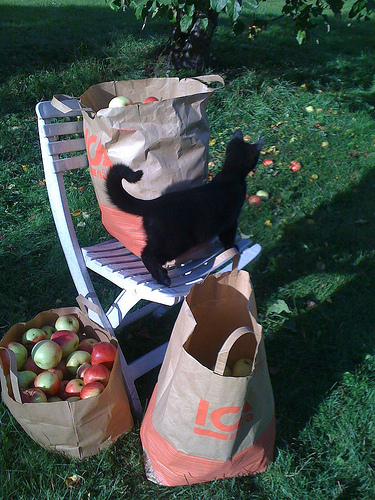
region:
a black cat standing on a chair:
[103, 125, 278, 291]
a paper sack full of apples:
[0, 293, 134, 463]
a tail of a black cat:
[103, 162, 148, 224]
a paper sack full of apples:
[50, 78, 221, 189]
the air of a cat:
[228, 124, 247, 145]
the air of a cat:
[250, 135, 270, 155]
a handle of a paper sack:
[213, 321, 260, 392]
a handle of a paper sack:
[71, 289, 118, 335]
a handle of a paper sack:
[45, 86, 90, 121]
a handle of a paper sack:
[198, 67, 226, 98]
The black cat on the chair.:
[103, 129, 271, 272]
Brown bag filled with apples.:
[1, 306, 132, 453]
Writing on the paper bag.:
[189, 393, 262, 441]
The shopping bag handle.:
[213, 321, 256, 377]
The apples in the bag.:
[16, 330, 104, 399]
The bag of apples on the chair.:
[56, 73, 226, 262]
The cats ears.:
[228, 113, 268, 153]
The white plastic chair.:
[34, 80, 241, 400]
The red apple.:
[290, 150, 304, 177]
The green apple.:
[108, 90, 129, 111]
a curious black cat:
[89, 121, 280, 275]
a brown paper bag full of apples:
[6, 309, 134, 469]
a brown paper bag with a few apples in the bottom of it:
[126, 268, 312, 497]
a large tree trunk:
[150, 7, 229, 82]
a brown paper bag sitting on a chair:
[40, 63, 224, 263]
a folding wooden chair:
[24, 92, 280, 425]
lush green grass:
[11, 8, 355, 491]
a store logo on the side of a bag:
[191, 395, 266, 455]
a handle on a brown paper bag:
[47, 78, 95, 127]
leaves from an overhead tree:
[136, 0, 367, 34]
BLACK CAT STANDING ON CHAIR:
[95, 129, 273, 284]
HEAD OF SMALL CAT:
[220, 122, 267, 180]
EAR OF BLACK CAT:
[250, 137, 270, 152]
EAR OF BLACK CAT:
[227, 125, 247, 141]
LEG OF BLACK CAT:
[138, 239, 177, 288]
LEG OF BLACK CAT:
[219, 221, 239, 250]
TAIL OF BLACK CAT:
[105, 158, 146, 215]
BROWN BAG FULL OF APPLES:
[4, 298, 135, 465]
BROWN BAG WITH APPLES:
[135, 267, 280, 490]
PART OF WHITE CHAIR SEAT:
[85, 244, 127, 277]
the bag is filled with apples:
[4, 300, 141, 465]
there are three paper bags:
[0, 65, 292, 490]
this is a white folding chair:
[31, 90, 257, 435]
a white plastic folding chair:
[32, 90, 258, 416]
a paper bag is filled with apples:
[4, 300, 130, 459]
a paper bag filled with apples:
[0, 293, 137, 466]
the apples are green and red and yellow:
[4, 305, 110, 399]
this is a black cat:
[93, 127, 282, 283]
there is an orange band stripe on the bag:
[92, 189, 219, 262]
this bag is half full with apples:
[137, 248, 295, 493]